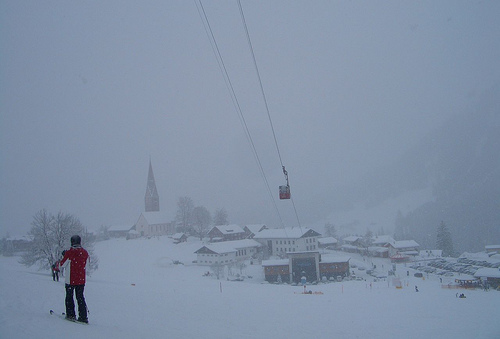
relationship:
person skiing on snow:
[52, 230, 97, 329] [18, 225, 495, 339]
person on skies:
[52, 230, 97, 329] [47, 304, 98, 325]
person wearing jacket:
[52, 230, 97, 329] [60, 249, 93, 288]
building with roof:
[260, 243, 354, 281] [322, 249, 345, 263]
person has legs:
[52, 230, 97, 329] [59, 282, 92, 320]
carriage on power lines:
[277, 179, 291, 200] [192, 1, 318, 239]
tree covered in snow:
[29, 200, 97, 270] [53, 190, 100, 226]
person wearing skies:
[52, 230, 97, 329] [47, 304, 98, 325]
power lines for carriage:
[192, 1, 318, 239] [277, 179, 291, 200]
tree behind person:
[29, 200, 97, 270] [52, 230, 97, 329]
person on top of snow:
[52, 230, 97, 329] [18, 225, 495, 339]